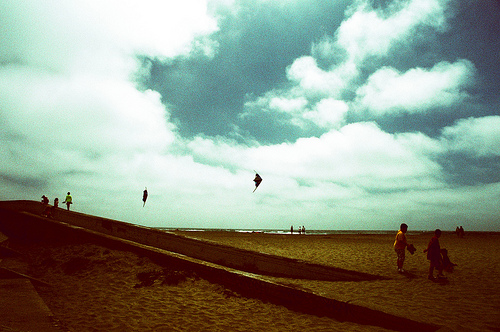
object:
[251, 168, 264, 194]
kite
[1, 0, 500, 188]
sky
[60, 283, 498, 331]
beach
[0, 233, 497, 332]
sand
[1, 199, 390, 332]
hill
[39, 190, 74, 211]
people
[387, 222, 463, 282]
people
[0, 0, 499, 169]
clouds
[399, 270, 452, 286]
shadow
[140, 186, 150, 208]
kite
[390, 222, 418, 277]
person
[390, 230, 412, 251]
yellow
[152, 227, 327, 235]
water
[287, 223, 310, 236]
people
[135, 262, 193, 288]
weeds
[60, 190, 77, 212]
person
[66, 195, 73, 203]
green